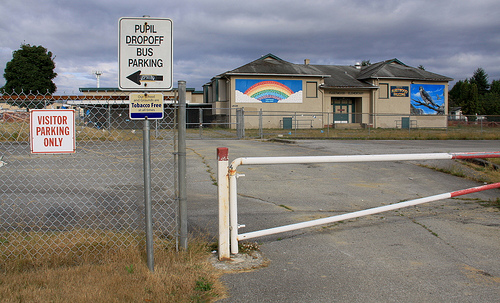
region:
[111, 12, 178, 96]
white metal "Pupil Dropoff Bus Parking" sign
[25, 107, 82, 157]
red-and-white "Visitor Parking Only" sign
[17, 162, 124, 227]
chain link fence on a background of concrete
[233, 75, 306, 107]
rainbow-and-clouds mural painted on a building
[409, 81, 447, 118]
blue bird mural painted on a building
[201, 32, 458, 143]
school building with murals painted on it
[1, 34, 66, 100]
large deciduous tree behind a chain-link fence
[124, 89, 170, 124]
blue-and-white "tobacco free" sign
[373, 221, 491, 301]
grey pavement driveway with cracks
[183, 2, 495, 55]
overcast sky with roiling dark clouds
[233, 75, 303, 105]
A mural of a rainbow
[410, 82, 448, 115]
A mural of a bird on a branch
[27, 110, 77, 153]
A sign declaring parking only for visitors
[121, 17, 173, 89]
A sign directing school dropoff and bus parking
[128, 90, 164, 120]
A sign declaring this area a tobacco free zone.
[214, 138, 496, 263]
A red and white gate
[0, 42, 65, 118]
A tall leafy tree at left in photo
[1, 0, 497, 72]
A dark and cloudy sky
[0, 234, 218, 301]
All the dead grass at lower left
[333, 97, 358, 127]
The building's green door with a red sign on it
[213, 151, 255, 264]
a white iron rod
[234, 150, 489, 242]
a white pol on road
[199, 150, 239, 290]
a straight white pole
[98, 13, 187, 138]
a white board with text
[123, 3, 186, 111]
black text in board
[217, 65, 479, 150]
a very big building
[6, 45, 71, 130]
a tree on the back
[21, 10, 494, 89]
a clear view of sky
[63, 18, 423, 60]
beautiful clouds in sky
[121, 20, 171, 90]
white sign on pole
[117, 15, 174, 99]
square white sign on pole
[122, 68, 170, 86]
black arrow on bottom of sign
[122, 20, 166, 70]
black writing on sign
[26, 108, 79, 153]
white and red sign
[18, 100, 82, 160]
white sign on metal fence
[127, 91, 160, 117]
small faded white sign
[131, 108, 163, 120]
blue line on bottom of sign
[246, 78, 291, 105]
rainbow painted on a a wall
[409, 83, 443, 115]
bird painted on a wall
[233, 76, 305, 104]
Rainbow mural on building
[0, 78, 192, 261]
Steel fence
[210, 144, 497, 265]
White and red barricade fence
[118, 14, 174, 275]
Sign on steel post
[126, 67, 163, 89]
Arrow pointing left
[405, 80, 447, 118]
Mural on side of building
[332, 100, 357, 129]
Doorway in building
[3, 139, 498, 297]
Cement parking lot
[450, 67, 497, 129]
Trees to the right of the building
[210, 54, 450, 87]
Gray roof of building